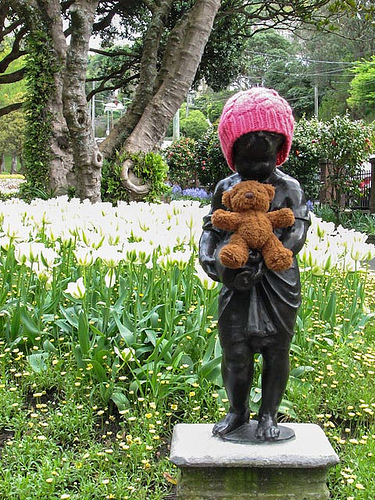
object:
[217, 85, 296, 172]
beanie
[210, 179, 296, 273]
stuffed animal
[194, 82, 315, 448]
statue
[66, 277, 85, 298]
flower petal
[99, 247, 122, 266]
flower petal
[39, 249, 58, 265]
flower petal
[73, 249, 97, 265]
flower petal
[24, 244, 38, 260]
flower petal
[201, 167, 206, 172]
rose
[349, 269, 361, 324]
stem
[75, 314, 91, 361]
stem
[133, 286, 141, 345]
stem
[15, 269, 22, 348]
stem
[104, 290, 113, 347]
stem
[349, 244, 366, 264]
daisy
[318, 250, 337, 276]
daisy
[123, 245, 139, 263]
daisy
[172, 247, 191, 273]
daisy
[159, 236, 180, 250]
daisy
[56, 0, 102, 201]
tree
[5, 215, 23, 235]
flowers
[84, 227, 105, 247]
flowers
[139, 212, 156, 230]
flowers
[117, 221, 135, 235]
flowers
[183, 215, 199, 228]
flowers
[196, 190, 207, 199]
flower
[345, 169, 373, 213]
hedge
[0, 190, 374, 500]
garden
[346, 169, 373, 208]
fence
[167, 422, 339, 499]
pedestal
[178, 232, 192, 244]
flower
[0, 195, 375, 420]
flower patch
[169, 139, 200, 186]
bush